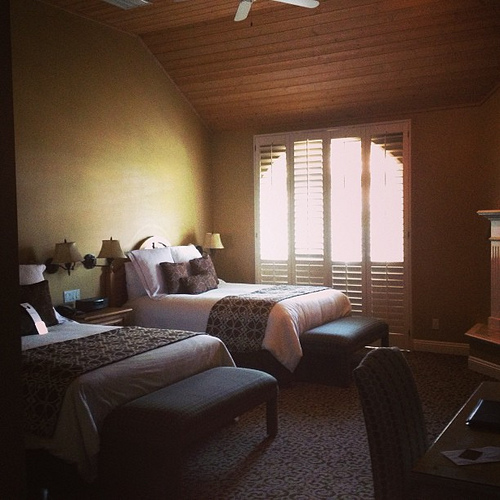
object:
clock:
[76, 296, 112, 313]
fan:
[234, 0, 322, 23]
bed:
[104, 234, 353, 374]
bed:
[18, 263, 240, 483]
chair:
[351, 346, 490, 500]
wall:
[11, 0, 215, 310]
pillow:
[159, 260, 191, 296]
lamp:
[50, 238, 85, 275]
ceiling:
[44, 0, 498, 139]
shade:
[251, 118, 415, 352]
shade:
[53, 242, 87, 266]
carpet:
[17, 345, 499, 499]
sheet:
[123, 282, 355, 373]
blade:
[234, 0, 255, 23]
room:
[0, 0, 498, 500]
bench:
[99, 363, 281, 491]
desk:
[411, 380, 500, 500]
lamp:
[95, 236, 128, 274]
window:
[258, 137, 410, 267]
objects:
[441, 397, 500, 468]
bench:
[299, 313, 391, 387]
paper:
[440, 445, 500, 468]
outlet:
[431, 318, 441, 331]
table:
[55, 303, 133, 328]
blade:
[268, 0, 321, 9]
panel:
[366, 118, 413, 355]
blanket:
[204, 284, 333, 358]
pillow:
[125, 243, 213, 299]